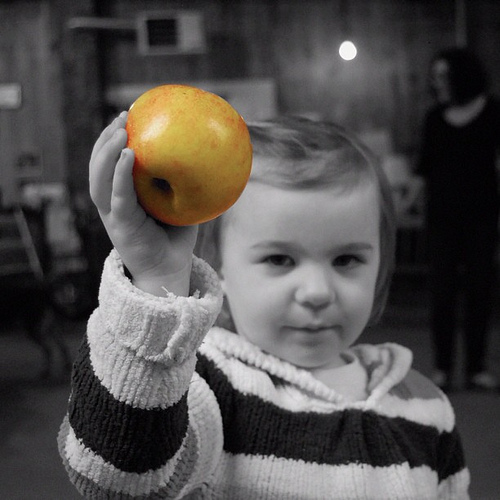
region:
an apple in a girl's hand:
[128, 83, 251, 225]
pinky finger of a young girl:
[111, 148, 138, 217]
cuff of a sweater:
[94, 246, 225, 368]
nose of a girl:
[294, 269, 336, 309]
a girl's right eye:
[255, 252, 297, 270]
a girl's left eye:
[328, 251, 366, 268]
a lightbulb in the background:
[337, 38, 357, 61]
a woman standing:
[397, 43, 498, 390]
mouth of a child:
[280, 317, 342, 339]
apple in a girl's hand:
[87, 80, 256, 298]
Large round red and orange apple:
[121, 83, 253, 226]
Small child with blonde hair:
[57, 83, 469, 496]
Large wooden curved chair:
[0, 201, 74, 376]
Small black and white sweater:
[58, 245, 472, 498]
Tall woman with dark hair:
[395, 45, 497, 393]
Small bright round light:
[338, 37, 357, 60]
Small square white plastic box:
[0, 83, 22, 109]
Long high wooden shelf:
[62, 18, 223, 39]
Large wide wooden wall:
[98, 0, 495, 146]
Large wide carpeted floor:
[1, 310, 496, 496]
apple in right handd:
[109, 87, 252, 227]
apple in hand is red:
[106, 73, 255, 234]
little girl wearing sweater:
[36, 243, 482, 499]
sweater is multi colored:
[41, 238, 486, 499]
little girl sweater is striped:
[51, 240, 479, 499]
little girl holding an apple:
[46, 70, 481, 498]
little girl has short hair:
[175, 99, 393, 331]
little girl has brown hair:
[186, 98, 400, 335]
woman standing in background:
[379, 38, 499, 395]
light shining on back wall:
[323, 28, 360, 65]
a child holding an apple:
[79, 38, 428, 490]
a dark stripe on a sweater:
[240, 406, 434, 470]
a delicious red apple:
[123, 82, 250, 229]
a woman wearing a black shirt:
[426, 45, 490, 374]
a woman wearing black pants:
[424, 51, 486, 386]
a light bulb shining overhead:
[329, 29, 374, 66]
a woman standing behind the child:
[417, 50, 494, 384]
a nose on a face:
[293, 270, 335, 310]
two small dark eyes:
[257, 246, 372, 278]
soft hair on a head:
[266, 117, 334, 154]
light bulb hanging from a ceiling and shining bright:
[336, 38, 357, 60]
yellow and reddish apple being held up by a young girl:
[129, 83, 254, 228]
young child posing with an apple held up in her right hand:
[57, 110, 471, 499]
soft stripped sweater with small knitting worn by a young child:
[56, 248, 471, 499]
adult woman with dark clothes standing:
[394, 47, 498, 394]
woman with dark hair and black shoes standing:
[393, 46, 499, 391]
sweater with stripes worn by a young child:
[57, 245, 469, 498]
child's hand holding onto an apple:
[86, 107, 200, 249]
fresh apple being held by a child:
[126, 83, 252, 228]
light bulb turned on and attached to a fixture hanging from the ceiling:
[336, 39, 357, 60]